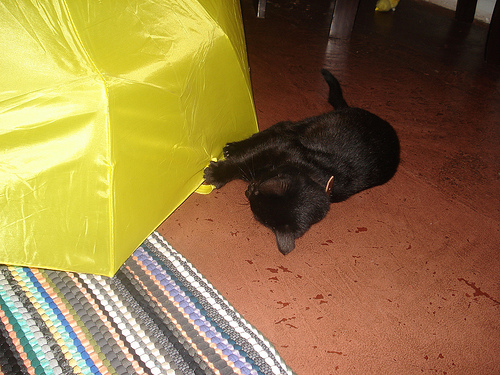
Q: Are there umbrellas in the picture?
A: Yes, there is an umbrella.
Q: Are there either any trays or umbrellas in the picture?
A: Yes, there is an umbrella.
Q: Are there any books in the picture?
A: No, there are no books.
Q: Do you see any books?
A: No, there are no books.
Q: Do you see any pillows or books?
A: No, there are no books or pillows.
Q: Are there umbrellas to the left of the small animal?
A: Yes, there is an umbrella to the left of the cat.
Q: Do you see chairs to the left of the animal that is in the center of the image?
A: No, there is an umbrella to the left of the cat.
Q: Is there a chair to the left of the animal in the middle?
A: No, there is an umbrella to the left of the cat.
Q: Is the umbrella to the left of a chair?
A: No, the umbrella is to the left of the cat.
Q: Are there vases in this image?
A: No, there are no vases.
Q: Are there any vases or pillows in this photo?
A: No, there are no vases or pillows.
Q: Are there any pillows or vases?
A: No, there are no vases or pillows.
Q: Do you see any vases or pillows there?
A: No, there are no vases or pillows.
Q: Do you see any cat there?
A: Yes, there is a cat.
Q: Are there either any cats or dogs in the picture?
A: Yes, there is a cat.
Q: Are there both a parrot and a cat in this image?
A: No, there is a cat but no parrots.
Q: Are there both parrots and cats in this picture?
A: No, there is a cat but no parrots.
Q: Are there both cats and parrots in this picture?
A: No, there is a cat but no parrots.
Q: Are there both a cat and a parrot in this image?
A: No, there is a cat but no parrots.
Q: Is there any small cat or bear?
A: Yes, there is a small cat.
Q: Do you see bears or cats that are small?
A: Yes, the cat is small.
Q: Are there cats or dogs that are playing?
A: Yes, the cat is playing.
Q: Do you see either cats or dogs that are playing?
A: Yes, the cat is playing.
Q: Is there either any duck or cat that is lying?
A: Yes, the cat is lying.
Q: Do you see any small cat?
A: Yes, there is a small cat.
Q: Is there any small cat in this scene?
A: Yes, there is a small cat.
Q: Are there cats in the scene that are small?
A: Yes, there is a cat that is small.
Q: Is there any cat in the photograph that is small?
A: Yes, there is a cat that is small.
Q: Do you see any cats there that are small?
A: Yes, there is a cat that is small.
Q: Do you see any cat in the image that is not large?
A: Yes, there is a small cat.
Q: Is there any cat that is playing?
A: Yes, there is a cat that is playing.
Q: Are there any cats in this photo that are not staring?
A: Yes, there is a cat that is playing.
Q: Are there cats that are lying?
A: Yes, there is a cat that is lying.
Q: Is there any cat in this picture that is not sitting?
A: Yes, there is a cat that is lying.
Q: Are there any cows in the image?
A: No, there are no cows.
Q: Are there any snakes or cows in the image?
A: No, there are no cows or snakes.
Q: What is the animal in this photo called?
A: The animal is a cat.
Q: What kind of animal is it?
A: The animal is a cat.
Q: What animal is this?
A: This is a cat.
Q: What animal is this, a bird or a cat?
A: This is a cat.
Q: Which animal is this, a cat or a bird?
A: This is a cat.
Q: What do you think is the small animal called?
A: The animal is a cat.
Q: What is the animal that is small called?
A: The animal is a cat.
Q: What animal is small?
A: The animal is a cat.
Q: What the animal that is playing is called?
A: The animal is a cat.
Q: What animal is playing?
A: The animal is a cat.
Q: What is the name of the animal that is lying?
A: The animal is a cat.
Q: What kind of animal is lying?
A: The animal is a cat.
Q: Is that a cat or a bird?
A: That is a cat.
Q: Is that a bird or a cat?
A: That is a cat.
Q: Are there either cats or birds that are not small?
A: No, there is a cat but it is small.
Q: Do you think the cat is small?
A: Yes, the cat is small.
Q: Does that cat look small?
A: Yes, the cat is small.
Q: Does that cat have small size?
A: Yes, the cat is small.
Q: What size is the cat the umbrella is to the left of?
A: The cat is small.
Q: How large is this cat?
A: The cat is small.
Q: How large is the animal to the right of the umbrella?
A: The cat is small.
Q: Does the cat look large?
A: No, the cat is small.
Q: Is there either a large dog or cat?
A: No, there is a cat but it is small.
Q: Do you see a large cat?
A: No, there is a cat but it is small.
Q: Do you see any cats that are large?
A: No, there is a cat but it is small.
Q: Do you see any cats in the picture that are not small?
A: No, there is a cat but it is small.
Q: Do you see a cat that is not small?
A: No, there is a cat but it is small.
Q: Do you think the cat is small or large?
A: The cat is small.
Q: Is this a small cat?
A: Yes, this is a small cat.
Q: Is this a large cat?
A: No, this is a small cat.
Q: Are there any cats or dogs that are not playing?
A: No, there is a cat but it is playing.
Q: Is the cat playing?
A: Yes, the cat is playing.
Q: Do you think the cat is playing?
A: Yes, the cat is playing.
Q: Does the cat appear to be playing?
A: Yes, the cat is playing.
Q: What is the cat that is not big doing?
A: The cat is playing.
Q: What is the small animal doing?
A: The cat is playing.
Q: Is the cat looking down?
A: No, the cat is playing.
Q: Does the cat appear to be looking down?
A: No, the cat is playing.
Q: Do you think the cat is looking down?
A: No, the cat is playing.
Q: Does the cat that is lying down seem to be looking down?
A: No, the cat is playing.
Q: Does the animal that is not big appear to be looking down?
A: No, the cat is playing.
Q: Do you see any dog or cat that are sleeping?
A: No, there is a cat but it is playing.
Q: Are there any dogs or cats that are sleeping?
A: No, there is a cat but it is playing.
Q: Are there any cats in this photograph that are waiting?
A: No, there is a cat but it is playing.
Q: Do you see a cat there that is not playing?
A: No, there is a cat but it is playing.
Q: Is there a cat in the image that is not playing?
A: No, there is a cat but it is playing.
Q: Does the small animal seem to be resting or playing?
A: The cat is playing.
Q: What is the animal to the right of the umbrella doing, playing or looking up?
A: The cat is playing.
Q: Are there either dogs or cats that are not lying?
A: No, there is a cat but it is lying.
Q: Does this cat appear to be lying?
A: Yes, the cat is lying.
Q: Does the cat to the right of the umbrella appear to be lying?
A: Yes, the cat is lying.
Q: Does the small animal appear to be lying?
A: Yes, the cat is lying.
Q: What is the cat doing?
A: The cat is lying.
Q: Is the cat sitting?
A: No, the cat is lying.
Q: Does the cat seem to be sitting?
A: No, the cat is lying.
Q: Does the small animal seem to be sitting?
A: No, the cat is lying.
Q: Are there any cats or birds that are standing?
A: No, there is a cat but it is lying.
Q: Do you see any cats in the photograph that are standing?
A: No, there is a cat but it is lying.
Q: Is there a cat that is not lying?
A: No, there is a cat but it is lying.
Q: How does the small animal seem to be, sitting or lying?
A: The cat is lying.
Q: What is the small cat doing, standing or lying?
A: The cat is lying.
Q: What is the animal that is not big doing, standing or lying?
A: The cat is lying.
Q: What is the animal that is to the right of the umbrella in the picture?
A: The animal is a cat.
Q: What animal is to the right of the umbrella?
A: The animal is a cat.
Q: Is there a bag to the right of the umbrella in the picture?
A: No, there is a cat to the right of the umbrella.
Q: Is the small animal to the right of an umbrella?
A: Yes, the cat is to the right of an umbrella.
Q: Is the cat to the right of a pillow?
A: No, the cat is to the right of an umbrella.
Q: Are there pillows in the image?
A: No, there are no pillows.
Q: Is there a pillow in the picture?
A: No, there are no pillows.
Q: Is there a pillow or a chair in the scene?
A: No, there are no pillows or chairs.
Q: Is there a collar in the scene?
A: Yes, there is a collar.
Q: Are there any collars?
A: Yes, there is a collar.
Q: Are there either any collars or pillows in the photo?
A: Yes, there is a collar.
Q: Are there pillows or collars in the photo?
A: Yes, there is a collar.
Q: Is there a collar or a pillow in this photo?
A: Yes, there is a collar.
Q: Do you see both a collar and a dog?
A: No, there is a collar but no dogs.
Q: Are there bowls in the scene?
A: No, there are no bowls.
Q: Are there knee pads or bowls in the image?
A: No, there are no bowls or knee pads.